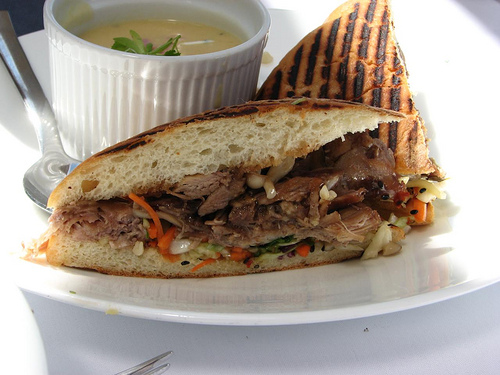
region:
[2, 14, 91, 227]
spoon on the plate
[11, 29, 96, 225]
spoon on the plate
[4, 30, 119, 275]
spoon on the plate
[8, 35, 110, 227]
spoon on the plate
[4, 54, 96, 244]
spoon on the plate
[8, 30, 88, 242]
spoon on the plate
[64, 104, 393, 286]
a slice of meat sandwich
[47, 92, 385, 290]
a slice of meat sandwich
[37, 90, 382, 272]
a slice of meat sandwich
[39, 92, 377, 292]
a slice of meat sandwich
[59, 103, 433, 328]
a slice of meat sandwich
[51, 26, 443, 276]
sandwiches on the plate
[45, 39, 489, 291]
sandwiches on the plate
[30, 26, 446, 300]
sandwiches on the plate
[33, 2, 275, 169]
this is a bowl of soup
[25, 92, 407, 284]
this is a sandwich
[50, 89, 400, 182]
this is a slice of bread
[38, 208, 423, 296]
this is a slice of bread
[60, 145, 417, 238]
beef stuffing in the sandwich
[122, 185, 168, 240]
a slice of carrot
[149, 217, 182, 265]
a slice of carrot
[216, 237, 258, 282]
a slice of carrot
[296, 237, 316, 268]
a slice of carrot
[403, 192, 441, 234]
a slice of carrot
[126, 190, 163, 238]
a piece of julienne carrot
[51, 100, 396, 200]
a toasted piece of bread on top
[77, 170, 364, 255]
cooked meat inside the sandwich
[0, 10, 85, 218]
a silver spoon on the plate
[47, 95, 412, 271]
an uneaten sandwich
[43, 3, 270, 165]
a white ramekin on the plate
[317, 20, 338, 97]
a toasted line on the sandwich bread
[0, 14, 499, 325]
the plate is white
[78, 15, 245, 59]
yellow soup inside ramekin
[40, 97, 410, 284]
Half of a sandwich with contents showing.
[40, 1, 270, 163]
A small round bowl with soup and green leaf inside.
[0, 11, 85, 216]
A silver spoon.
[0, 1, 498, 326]
A white round plate.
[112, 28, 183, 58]
Green leaf in the soup.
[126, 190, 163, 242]
Thin carrot slice going from inside the sandwich to the top bun.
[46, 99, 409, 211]
Top piece of bread of the most visible sandwich.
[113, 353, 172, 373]
Silver tines of a barely visible fork.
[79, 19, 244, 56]
Dull orange soup.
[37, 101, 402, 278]
Small half of sandwich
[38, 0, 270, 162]
Small bowl of creamy onion soup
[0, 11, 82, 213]
Long silver metal spoon